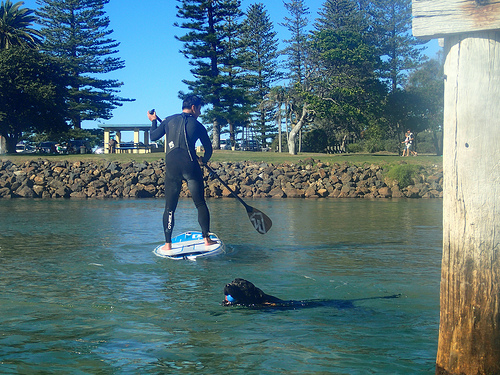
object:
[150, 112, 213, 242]
wet suit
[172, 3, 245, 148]
tree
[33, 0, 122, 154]
tree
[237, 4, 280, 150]
tree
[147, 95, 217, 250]
man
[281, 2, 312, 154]
tree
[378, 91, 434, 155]
tree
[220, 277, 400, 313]
dog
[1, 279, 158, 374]
water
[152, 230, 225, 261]
board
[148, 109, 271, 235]
paddle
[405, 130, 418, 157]
person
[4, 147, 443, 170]
grass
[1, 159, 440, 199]
rocks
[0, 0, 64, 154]
tree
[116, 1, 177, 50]
sky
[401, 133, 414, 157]
person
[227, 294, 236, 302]
blue ball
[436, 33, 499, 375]
pole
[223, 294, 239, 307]
mouth